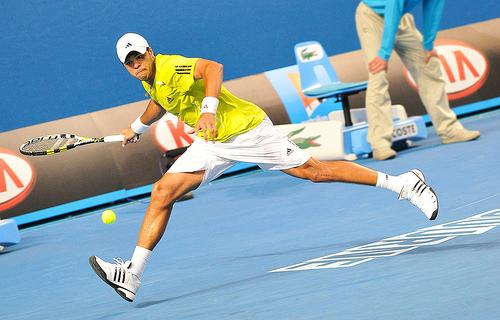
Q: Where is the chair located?
A: Behind the line judge.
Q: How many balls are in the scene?
A: One.